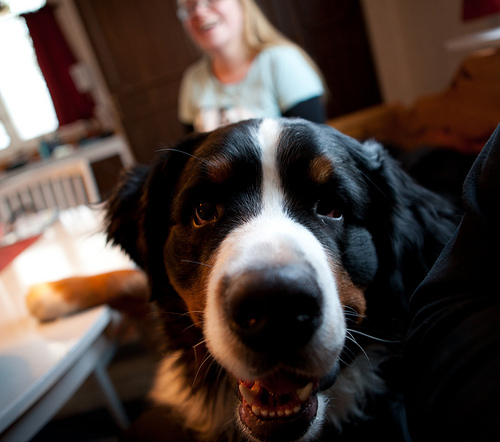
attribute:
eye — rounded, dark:
[187, 197, 219, 226]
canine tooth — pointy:
[299, 380, 313, 401]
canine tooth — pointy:
[231, 382, 258, 404]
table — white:
[6, 338, 53, 377]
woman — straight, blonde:
[178, 1, 327, 135]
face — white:
[145, 130, 367, 375]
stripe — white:
[252, 114, 292, 223]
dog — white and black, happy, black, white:
[99, 121, 452, 438]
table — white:
[7, 205, 126, 437]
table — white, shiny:
[5, 190, 163, 420]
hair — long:
[174, 0, 329, 105]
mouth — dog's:
[212, 347, 341, 437]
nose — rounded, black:
[220, 255, 320, 354]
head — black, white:
[153, 116, 390, 440]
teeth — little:
[251, 404, 301, 418]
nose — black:
[224, 264, 324, 353]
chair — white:
[2, 153, 104, 232]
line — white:
[253, 113, 285, 211]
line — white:
[252, 114, 292, 217]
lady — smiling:
[171, 2, 333, 119]